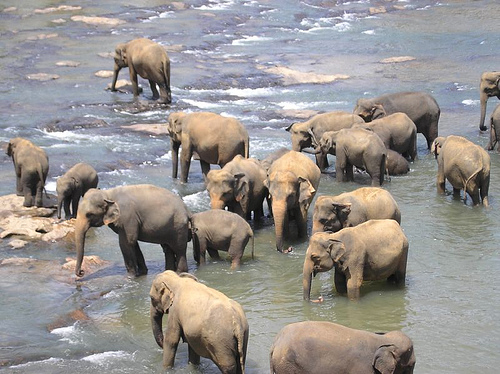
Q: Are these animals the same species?
A: Yes, all the animals are elephants.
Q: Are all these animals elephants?
A: Yes, all the animals are elephants.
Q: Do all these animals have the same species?
A: Yes, all the animals are elephants.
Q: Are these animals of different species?
A: No, all the animals are elephants.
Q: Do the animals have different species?
A: No, all the animals are elephants.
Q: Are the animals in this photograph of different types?
A: No, all the animals are elephants.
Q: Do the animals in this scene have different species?
A: No, all the animals are elephants.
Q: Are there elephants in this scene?
A: Yes, there is an elephant.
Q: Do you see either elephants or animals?
A: Yes, there is an elephant.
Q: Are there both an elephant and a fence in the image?
A: No, there is an elephant but no fences.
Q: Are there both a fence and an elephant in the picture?
A: No, there is an elephant but no fences.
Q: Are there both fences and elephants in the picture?
A: No, there is an elephant but no fences.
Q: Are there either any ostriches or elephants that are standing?
A: Yes, the elephant is standing.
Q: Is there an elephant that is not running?
A: Yes, there is an elephant that is standing.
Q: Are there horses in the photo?
A: No, there are no horses.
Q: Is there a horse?
A: No, there are no horses.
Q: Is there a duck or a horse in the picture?
A: No, there are no horses or ducks.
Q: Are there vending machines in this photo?
A: No, there are no vending machines.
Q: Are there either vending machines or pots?
A: No, there are no vending machines or pots.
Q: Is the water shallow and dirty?
A: Yes, the water is shallow and dirty.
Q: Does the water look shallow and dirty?
A: Yes, the water is shallow and dirty.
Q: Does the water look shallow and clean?
A: No, the water is shallow but dirty.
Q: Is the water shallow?
A: Yes, the water is shallow.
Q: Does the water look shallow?
A: Yes, the water is shallow.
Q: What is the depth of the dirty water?
A: The water is shallow.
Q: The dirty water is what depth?
A: The water is shallow.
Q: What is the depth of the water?
A: The water is shallow.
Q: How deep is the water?
A: The water is shallow.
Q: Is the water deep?
A: No, the water is shallow.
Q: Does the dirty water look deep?
A: No, the water is shallow.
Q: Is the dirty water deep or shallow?
A: The water is shallow.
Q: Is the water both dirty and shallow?
A: Yes, the water is dirty and shallow.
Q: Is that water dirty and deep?
A: No, the water is dirty but shallow.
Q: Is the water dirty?
A: Yes, the water is dirty.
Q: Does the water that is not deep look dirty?
A: Yes, the water is dirty.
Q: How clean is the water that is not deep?
A: The water is dirty.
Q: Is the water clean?
A: No, the water is dirty.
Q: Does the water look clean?
A: No, the water is dirty.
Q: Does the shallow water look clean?
A: No, the water is dirty.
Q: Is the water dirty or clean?
A: The water is dirty.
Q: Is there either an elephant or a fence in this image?
A: Yes, there is an elephant.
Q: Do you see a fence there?
A: No, there are no fences.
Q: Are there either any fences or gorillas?
A: No, there are no fences or gorillas.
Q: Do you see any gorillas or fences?
A: No, there are no fences or gorillas.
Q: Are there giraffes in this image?
A: No, there are no giraffes.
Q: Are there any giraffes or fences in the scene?
A: No, there are no giraffes or fences.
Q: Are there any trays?
A: No, there are no trays.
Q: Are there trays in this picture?
A: No, there are no trays.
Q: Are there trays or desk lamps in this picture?
A: No, there are no trays or desk lamps.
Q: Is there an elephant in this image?
A: Yes, there is an elephant.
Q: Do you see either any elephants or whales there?
A: Yes, there is an elephant.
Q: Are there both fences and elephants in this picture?
A: No, there is an elephant but no fences.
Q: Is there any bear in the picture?
A: No, there are no bears.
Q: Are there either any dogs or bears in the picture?
A: No, there are no bears or dogs.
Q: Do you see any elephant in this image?
A: Yes, there is an elephant.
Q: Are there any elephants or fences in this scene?
A: Yes, there is an elephant.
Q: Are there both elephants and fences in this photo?
A: No, there is an elephant but no fences.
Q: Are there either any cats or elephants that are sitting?
A: Yes, the elephant is sitting.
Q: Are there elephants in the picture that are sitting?
A: Yes, there is an elephant that is sitting.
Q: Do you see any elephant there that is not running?
A: Yes, there is an elephant that is sitting .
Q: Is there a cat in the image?
A: No, there are no cats.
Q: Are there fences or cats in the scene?
A: No, there are no cats or fences.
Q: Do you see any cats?
A: No, there are no cats.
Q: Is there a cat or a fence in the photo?
A: No, there are no cats or fences.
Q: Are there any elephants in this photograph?
A: Yes, there is an elephant.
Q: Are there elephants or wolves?
A: Yes, there is an elephant.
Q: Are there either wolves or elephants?
A: Yes, there is an elephant.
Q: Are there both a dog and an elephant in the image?
A: No, there is an elephant but no dogs.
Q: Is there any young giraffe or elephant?
A: Yes, there is a young elephant.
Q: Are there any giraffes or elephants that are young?
A: Yes, the elephant is young.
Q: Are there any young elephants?
A: Yes, there is a young elephant.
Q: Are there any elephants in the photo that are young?
A: Yes, there is an elephant that is young.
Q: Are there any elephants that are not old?
A: Yes, there is an young elephant.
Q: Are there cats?
A: No, there are no cats.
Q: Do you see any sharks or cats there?
A: No, there are no cats or sharks.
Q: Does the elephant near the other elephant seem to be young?
A: Yes, the elephant is young.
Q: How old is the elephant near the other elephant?
A: The elephant is young.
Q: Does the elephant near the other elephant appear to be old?
A: No, the elephant is young.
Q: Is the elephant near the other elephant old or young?
A: The elephant is young.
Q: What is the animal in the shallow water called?
A: The animal is an elephant.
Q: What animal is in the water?
A: The animal is an elephant.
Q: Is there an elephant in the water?
A: Yes, there is an elephant in the water.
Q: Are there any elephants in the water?
A: Yes, there is an elephant in the water.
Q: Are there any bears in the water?
A: No, there is an elephant in the water.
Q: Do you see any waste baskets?
A: No, there are no waste baskets.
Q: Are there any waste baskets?
A: No, there are no waste baskets.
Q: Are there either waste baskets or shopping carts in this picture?
A: No, there are no waste baskets or shopping carts.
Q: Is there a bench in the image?
A: No, there are no benches.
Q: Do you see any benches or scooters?
A: No, there are no benches or scooters.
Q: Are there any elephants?
A: Yes, there is an elephant.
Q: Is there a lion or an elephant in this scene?
A: Yes, there is an elephant.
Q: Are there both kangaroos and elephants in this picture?
A: No, there is an elephant but no kangaroos.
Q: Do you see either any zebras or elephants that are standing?
A: Yes, the elephant is standing.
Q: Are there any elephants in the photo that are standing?
A: Yes, there is an elephant that is standing.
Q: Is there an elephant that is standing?
A: Yes, there is an elephant that is standing.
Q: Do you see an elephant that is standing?
A: Yes, there is an elephant that is standing.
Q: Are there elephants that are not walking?
A: Yes, there is an elephant that is standing.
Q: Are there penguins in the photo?
A: No, there are no penguins.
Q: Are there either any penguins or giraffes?
A: No, there are no penguins or giraffes.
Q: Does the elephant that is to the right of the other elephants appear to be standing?
A: Yes, the elephant is standing.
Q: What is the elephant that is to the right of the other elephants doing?
A: The elephant is standing.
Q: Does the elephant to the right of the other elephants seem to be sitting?
A: No, the elephant is standing.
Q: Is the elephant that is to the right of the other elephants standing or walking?
A: The elephant is standing.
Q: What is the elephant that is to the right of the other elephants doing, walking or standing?
A: The elephant is standing.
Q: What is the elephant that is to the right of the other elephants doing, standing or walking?
A: The elephant is standing.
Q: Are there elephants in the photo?
A: Yes, there is an elephant.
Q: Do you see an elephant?
A: Yes, there is an elephant.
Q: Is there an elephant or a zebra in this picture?
A: Yes, there is an elephant.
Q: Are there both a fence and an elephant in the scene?
A: No, there is an elephant but no fences.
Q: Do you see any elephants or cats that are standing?
A: Yes, the elephant is standing.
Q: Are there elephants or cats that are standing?
A: Yes, the elephant is standing.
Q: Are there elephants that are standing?
A: Yes, there is an elephant that is standing.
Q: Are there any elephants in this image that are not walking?
A: Yes, there is an elephant that is standing.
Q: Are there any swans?
A: No, there are no swans.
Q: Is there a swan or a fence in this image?
A: No, there are no swans or fences.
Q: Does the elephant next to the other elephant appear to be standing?
A: Yes, the elephant is standing.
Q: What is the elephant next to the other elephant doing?
A: The elephant is standing.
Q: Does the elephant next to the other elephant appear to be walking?
A: No, the elephant is standing.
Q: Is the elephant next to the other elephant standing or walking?
A: The elephant is standing.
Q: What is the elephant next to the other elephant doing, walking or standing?
A: The elephant is standing.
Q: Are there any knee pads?
A: No, there are no knee pads.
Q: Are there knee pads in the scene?
A: No, there are no knee pads.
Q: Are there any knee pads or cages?
A: No, there are no knee pads or cages.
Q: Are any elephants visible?
A: Yes, there are elephants.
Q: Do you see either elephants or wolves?
A: Yes, there are elephants.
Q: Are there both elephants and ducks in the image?
A: No, there are elephants but no ducks.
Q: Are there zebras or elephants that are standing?
A: Yes, the elephants are standing.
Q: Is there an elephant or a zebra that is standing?
A: Yes, the elephants are standing.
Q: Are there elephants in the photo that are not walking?
A: Yes, there are elephants that are standing.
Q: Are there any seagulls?
A: No, there are no seagulls.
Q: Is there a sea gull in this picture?
A: No, there are no seagulls.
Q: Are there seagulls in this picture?
A: No, there are no seagulls.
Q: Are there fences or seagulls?
A: No, there are no seagulls or fences.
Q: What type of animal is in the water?
A: The animals are elephants.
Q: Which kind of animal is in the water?
A: The animals are elephants.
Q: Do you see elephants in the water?
A: Yes, there are elephants in the water.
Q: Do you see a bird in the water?
A: No, there are elephants in the water.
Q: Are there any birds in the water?
A: No, there are elephants in the water.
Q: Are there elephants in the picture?
A: Yes, there is an elephant.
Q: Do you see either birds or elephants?
A: Yes, there is an elephant.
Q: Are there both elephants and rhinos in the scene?
A: No, there is an elephant but no rhinos.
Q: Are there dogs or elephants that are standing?
A: Yes, the elephant is standing.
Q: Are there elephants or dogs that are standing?
A: Yes, the elephant is standing.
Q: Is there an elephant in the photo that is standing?
A: Yes, there is an elephant that is standing.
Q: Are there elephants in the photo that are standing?
A: Yes, there is an elephant that is standing.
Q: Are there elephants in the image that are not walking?
A: Yes, there is an elephant that is standing.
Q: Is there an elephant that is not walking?
A: Yes, there is an elephant that is standing.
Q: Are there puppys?
A: No, there are no puppys.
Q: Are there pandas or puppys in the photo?
A: No, there are no puppys or pandas.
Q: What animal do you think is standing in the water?
A: The elephant is standing in the water.